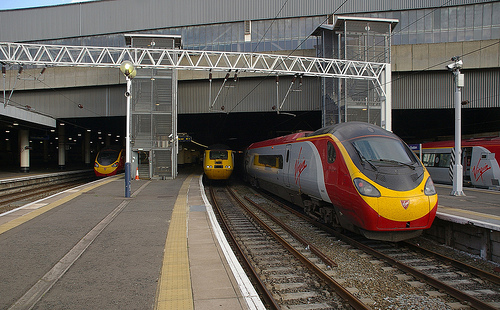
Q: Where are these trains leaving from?
A: A train station.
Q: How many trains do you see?
A: Four trains.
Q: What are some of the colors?
A: Grey, white, Red, Yellow and black.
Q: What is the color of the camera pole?
A: White.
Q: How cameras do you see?
A: One camera.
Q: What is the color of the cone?
A: Orange and white.